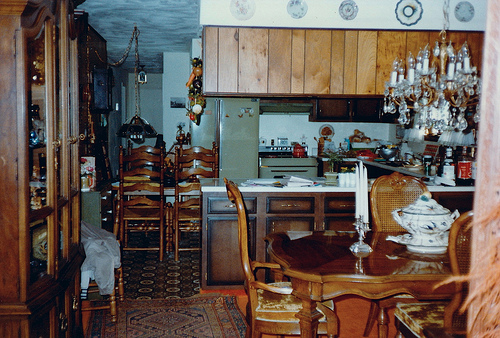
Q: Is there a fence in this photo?
A: No, there are no fences.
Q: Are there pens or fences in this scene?
A: No, there are no fences or pens.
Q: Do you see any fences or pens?
A: No, there are no fences or pens.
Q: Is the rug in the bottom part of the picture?
A: Yes, the rug is in the bottom of the image.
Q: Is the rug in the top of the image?
A: No, the rug is in the bottom of the image.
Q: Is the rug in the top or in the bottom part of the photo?
A: The rug is in the bottom of the image.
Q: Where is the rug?
A: The rug is on the floor.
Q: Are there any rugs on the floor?
A: Yes, there is a rug on the floor.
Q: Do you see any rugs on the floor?
A: Yes, there is a rug on the floor.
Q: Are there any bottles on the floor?
A: No, there is a rug on the floor.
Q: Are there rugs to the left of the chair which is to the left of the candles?
A: Yes, there is a rug to the left of the chair.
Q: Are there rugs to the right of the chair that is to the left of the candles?
A: No, the rug is to the left of the chair.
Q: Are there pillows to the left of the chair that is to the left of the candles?
A: No, there is a rug to the left of the chair.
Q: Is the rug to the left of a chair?
A: Yes, the rug is to the left of a chair.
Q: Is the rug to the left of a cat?
A: No, the rug is to the left of a chair.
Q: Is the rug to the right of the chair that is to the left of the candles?
A: No, the rug is to the left of the chair.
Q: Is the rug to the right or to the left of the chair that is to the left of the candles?
A: The rug is to the left of the chair.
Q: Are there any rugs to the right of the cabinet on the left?
A: Yes, there is a rug to the right of the cabinet.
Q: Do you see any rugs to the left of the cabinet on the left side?
A: No, the rug is to the right of the cabinet.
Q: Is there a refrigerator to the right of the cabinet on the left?
A: No, there is a rug to the right of the cabinet.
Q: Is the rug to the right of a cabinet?
A: Yes, the rug is to the right of a cabinet.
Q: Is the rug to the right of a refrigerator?
A: No, the rug is to the right of a cabinet.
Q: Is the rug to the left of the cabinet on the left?
A: No, the rug is to the right of the cabinet.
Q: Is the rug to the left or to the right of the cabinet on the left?
A: The rug is to the right of the cabinet.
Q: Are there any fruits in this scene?
A: Yes, there is a fruit.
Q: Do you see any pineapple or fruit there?
A: Yes, there is a fruit.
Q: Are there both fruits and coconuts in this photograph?
A: No, there is a fruit but no coconuts.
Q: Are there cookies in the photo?
A: No, there are no cookies.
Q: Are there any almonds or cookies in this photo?
A: No, there are no cookies or almonds.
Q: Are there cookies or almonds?
A: No, there are no cookies or almonds.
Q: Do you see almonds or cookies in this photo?
A: No, there are no cookies or almonds.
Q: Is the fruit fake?
A: Yes, the fruit is fake.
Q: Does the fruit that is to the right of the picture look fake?
A: Yes, the fruit is fake.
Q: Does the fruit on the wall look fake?
A: Yes, the fruit is fake.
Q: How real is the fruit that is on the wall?
A: The fruit is fake.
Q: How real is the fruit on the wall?
A: The fruit is fake.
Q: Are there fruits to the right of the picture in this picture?
A: Yes, there is a fruit to the right of the picture.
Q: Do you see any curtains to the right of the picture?
A: No, there is a fruit to the right of the picture.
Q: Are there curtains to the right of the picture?
A: No, there is a fruit to the right of the picture.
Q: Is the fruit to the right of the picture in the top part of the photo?
A: Yes, the fruit is to the right of the picture.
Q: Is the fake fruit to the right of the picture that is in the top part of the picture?
A: Yes, the fruit is to the right of the picture.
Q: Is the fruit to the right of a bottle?
A: No, the fruit is to the right of the picture.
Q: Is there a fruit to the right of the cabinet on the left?
A: Yes, there is a fruit to the right of the cabinet.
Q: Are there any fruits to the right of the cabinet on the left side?
A: Yes, there is a fruit to the right of the cabinet.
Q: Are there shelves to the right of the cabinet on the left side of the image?
A: No, there is a fruit to the right of the cabinet.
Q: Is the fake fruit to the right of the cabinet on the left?
A: Yes, the fruit is to the right of the cabinet.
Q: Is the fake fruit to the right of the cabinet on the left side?
A: Yes, the fruit is to the right of the cabinet.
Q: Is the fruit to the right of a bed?
A: No, the fruit is to the right of the cabinet.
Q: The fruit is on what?
A: The fruit is on the wall.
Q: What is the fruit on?
A: The fruit is on the wall.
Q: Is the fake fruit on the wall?
A: Yes, the fruit is on the wall.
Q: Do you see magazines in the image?
A: No, there are no magazines.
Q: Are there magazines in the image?
A: No, there are no magazines.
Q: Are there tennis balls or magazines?
A: No, there are no magazines or tennis balls.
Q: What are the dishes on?
A: The dishes are on the wall.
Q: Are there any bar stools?
A: No, there are no bar stools.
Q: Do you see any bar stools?
A: No, there are no bar stools.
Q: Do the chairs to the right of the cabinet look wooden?
A: Yes, the chairs are wooden.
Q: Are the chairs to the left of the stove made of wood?
A: Yes, the chairs are made of wood.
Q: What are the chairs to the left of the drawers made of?
A: The chairs are made of wood.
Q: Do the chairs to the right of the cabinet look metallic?
A: No, the chairs are wooden.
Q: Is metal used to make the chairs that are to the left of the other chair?
A: No, the chairs are made of wood.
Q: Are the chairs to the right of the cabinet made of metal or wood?
A: The chairs are made of wood.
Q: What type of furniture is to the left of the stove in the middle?
A: The pieces of furniture are chairs.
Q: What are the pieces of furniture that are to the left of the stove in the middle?
A: The pieces of furniture are chairs.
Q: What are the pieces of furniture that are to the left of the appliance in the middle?
A: The pieces of furniture are chairs.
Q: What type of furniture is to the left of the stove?
A: The pieces of furniture are chairs.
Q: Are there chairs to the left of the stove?
A: Yes, there are chairs to the left of the stove.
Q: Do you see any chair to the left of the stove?
A: Yes, there are chairs to the left of the stove.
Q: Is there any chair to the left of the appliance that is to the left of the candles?
A: Yes, there are chairs to the left of the stove.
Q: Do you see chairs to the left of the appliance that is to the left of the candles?
A: Yes, there are chairs to the left of the stove.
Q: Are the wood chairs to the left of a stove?
A: Yes, the chairs are to the left of a stove.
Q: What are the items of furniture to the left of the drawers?
A: The pieces of furniture are chairs.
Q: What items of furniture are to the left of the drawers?
A: The pieces of furniture are chairs.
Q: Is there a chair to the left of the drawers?
A: Yes, there are chairs to the left of the drawers.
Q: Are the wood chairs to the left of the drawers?
A: Yes, the chairs are to the left of the drawers.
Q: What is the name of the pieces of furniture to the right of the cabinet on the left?
A: The pieces of furniture are chairs.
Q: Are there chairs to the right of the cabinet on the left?
A: Yes, there are chairs to the right of the cabinet.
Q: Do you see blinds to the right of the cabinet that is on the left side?
A: No, there are chairs to the right of the cabinet.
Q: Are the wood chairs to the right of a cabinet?
A: Yes, the chairs are to the right of a cabinet.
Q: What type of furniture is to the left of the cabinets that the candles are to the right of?
A: The pieces of furniture are chairs.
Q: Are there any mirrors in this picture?
A: No, there are no mirrors.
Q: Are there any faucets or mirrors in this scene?
A: No, there are no mirrors or faucets.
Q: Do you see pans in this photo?
A: No, there are no pans.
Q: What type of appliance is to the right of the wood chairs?
A: The appliance is a stove.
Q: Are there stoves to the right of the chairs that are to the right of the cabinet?
A: Yes, there is a stove to the right of the chairs.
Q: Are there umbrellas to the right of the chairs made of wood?
A: No, there is a stove to the right of the chairs.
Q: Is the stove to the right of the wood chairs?
A: Yes, the stove is to the right of the chairs.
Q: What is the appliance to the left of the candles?
A: The appliance is a stove.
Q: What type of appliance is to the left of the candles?
A: The appliance is a stove.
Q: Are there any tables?
A: Yes, there is a table.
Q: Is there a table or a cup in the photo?
A: Yes, there is a table.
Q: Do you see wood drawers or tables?
A: Yes, there is a wood table.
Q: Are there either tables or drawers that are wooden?
A: Yes, the table is wooden.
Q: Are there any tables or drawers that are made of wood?
A: Yes, the table is made of wood.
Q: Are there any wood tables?
A: Yes, there is a wood table.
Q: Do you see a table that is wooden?
A: Yes, there is a table that is wooden.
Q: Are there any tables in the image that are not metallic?
A: Yes, there is a wooden table.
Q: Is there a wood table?
A: Yes, there is a table that is made of wood.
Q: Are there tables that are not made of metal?
A: Yes, there is a table that is made of wood.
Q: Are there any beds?
A: No, there are no beds.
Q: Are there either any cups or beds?
A: No, there are no beds or cups.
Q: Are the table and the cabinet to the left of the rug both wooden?
A: Yes, both the table and the cabinet are wooden.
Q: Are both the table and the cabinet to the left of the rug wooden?
A: Yes, both the table and the cabinet are wooden.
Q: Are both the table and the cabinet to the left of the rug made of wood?
A: Yes, both the table and the cabinet are made of wood.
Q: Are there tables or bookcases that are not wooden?
A: No, there is a table but it is wooden.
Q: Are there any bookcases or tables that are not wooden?
A: No, there is a table but it is wooden.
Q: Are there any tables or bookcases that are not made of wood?
A: No, there is a table but it is made of wood.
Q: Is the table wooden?
A: Yes, the table is wooden.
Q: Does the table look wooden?
A: Yes, the table is wooden.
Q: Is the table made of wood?
A: Yes, the table is made of wood.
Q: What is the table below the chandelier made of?
A: The table is made of wood.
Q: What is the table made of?
A: The table is made of wood.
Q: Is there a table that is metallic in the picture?
A: No, there is a table but it is wooden.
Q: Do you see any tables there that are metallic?
A: No, there is a table but it is wooden.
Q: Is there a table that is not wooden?
A: No, there is a table but it is wooden.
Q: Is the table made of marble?
A: No, the table is made of wood.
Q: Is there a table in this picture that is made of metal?
A: No, there is a table but it is made of wood.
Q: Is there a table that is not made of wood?
A: No, there is a table but it is made of wood.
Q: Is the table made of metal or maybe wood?
A: The table is made of wood.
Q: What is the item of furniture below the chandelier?
A: The piece of furniture is a table.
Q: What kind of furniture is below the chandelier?
A: The piece of furniture is a table.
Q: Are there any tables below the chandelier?
A: Yes, there is a table below the chandelier.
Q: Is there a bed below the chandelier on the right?
A: No, there is a table below the chandelier.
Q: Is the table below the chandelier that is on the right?
A: Yes, the table is below the chandelier.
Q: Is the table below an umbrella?
A: No, the table is below the chandelier.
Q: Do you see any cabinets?
A: Yes, there is a cabinet.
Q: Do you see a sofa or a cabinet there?
A: Yes, there is a cabinet.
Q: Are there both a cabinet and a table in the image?
A: Yes, there are both a cabinet and a table.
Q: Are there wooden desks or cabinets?
A: Yes, there is a wood cabinet.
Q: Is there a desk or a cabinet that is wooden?
A: Yes, the cabinet is wooden.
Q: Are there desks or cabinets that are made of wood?
A: Yes, the cabinet is made of wood.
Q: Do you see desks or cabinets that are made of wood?
A: Yes, the cabinet is made of wood.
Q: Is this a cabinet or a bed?
A: This is a cabinet.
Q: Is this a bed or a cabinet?
A: This is a cabinet.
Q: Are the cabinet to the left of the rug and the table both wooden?
A: Yes, both the cabinet and the table are wooden.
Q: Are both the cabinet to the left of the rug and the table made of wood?
A: Yes, both the cabinet and the table are made of wood.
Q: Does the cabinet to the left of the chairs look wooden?
A: Yes, the cabinet is wooden.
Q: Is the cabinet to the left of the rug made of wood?
A: Yes, the cabinet is made of wood.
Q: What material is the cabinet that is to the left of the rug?
A: The cabinet is made of wood.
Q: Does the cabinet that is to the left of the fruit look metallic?
A: No, the cabinet is wooden.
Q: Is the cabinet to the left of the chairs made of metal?
A: No, the cabinet is made of wood.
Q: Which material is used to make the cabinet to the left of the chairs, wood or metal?
A: The cabinet is made of wood.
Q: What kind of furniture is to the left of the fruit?
A: The piece of furniture is a cabinet.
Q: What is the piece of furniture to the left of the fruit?
A: The piece of furniture is a cabinet.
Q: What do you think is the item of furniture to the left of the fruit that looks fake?
A: The piece of furniture is a cabinet.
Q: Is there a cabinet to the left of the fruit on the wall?
A: Yes, there is a cabinet to the left of the fruit.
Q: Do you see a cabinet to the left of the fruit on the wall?
A: Yes, there is a cabinet to the left of the fruit.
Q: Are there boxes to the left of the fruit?
A: No, there is a cabinet to the left of the fruit.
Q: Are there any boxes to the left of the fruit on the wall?
A: No, there is a cabinet to the left of the fruit.